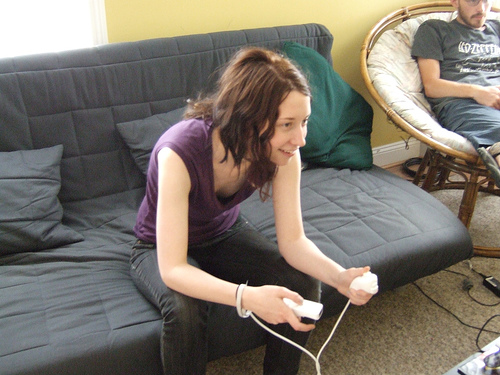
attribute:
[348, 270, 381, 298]
controller — white, wii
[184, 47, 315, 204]
hair — brown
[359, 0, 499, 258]
chair — large, brown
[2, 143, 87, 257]
pillow — black, grey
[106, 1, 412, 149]
wall — yellow, brown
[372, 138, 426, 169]
trim — white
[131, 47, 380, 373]
girl — sitting, holding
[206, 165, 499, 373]
carpet — section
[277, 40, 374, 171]
pillow — green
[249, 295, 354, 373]
cord — white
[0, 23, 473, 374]
sofa — black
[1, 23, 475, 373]
couch — grey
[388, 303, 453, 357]
floor — brown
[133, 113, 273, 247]
shirt — purple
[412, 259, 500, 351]
wires — black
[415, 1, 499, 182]
man — sitting, playing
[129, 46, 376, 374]
woman — sitting, playing, young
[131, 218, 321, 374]
jeans — black